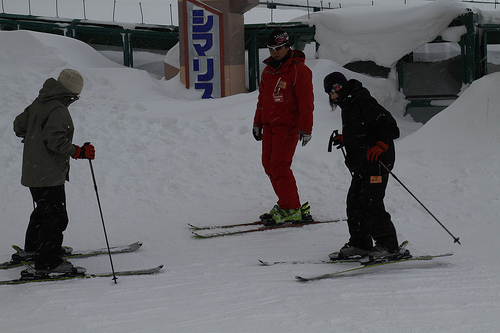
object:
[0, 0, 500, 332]
snow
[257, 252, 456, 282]
skis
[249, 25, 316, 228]
man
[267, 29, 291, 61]
head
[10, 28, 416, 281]
people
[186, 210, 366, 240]
ski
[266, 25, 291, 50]
hat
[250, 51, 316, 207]
suit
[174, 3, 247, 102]
sign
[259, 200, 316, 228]
boot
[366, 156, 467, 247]
pole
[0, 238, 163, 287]
ski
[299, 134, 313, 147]
glove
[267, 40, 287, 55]
sun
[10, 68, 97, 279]
skier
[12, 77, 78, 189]
jacket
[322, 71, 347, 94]
cap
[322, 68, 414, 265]
woman